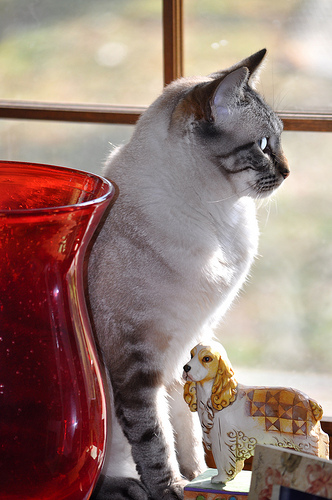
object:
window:
[1, 3, 331, 452]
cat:
[95, 47, 309, 491]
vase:
[0, 154, 117, 499]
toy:
[182, 343, 331, 481]